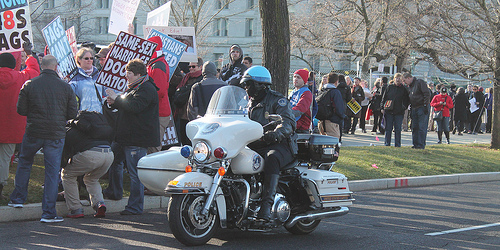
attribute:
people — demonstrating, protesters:
[0, 43, 499, 224]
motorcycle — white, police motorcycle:
[135, 86, 355, 245]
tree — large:
[260, 0, 290, 97]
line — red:
[394, 179, 399, 189]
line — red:
[399, 179, 406, 187]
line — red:
[404, 177, 409, 186]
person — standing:
[2, 41, 42, 204]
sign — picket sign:
[0, 1, 34, 53]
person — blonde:
[67, 47, 109, 115]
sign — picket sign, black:
[39, 15, 80, 83]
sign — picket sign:
[95, 31, 157, 92]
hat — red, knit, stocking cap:
[294, 68, 311, 84]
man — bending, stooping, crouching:
[64, 124, 113, 219]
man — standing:
[350, 76, 364, 135]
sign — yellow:
[346, 96, 362, 115]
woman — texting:
[430, 85, 454, 141]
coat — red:
[431, 95, 455, 118]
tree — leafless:
[288, 1, 499, 147]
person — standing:
[469, 85, 484, 134]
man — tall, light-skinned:
[217, 44, 247, 83]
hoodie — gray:
[219, 43, 245, 85]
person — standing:
[380, 72, 409, 146]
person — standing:
[316, 72, 342, 154]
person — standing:
[402, 72, 432, 148]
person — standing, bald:
[16, 55, 79, 223]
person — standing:
[103, 60, 159, 214]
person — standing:
[187, 59, 229, 119]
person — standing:
[147, 37, 175, 149]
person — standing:
[174, 56, 207, 143]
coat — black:
[15, 70, 81, 136]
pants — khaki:
[62, 148, 119, 208]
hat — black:
[440, 87, 448, 94]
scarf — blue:
[290, 87, 310, 110]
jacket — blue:
[69, 67, 107, 114]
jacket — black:
[114, 80, 162, 147]